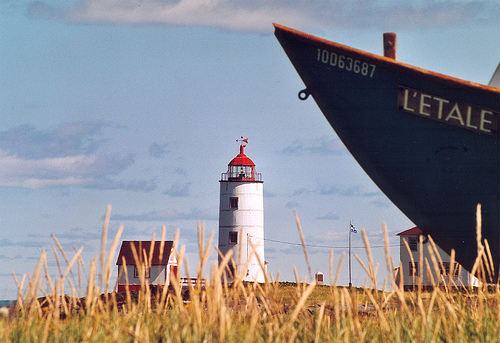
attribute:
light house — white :
[217, 135, 265, 285]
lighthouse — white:
[214, 130, 270, 282]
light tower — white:
[218, 134, 267, 289]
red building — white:
[116, 240, 179, 292]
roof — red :
[114, 238, 177, 265]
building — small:
[108, 238, 178, 300]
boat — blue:
[274, 21, 498, 282]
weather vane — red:
[233, 135, 250, 147]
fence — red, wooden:
[179, 276, 206, 286]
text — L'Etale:
[382, 82, 490, 136]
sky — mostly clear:
[0, 0, 499, 297]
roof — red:
[227, 145, 256, 167]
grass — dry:
[209, 283, 442, 341]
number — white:
[313, 52, 381, 82]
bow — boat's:
[272, 22, 498, 284]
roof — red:
[113, 235, 189, 272]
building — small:
[108, 233, 186, 291]